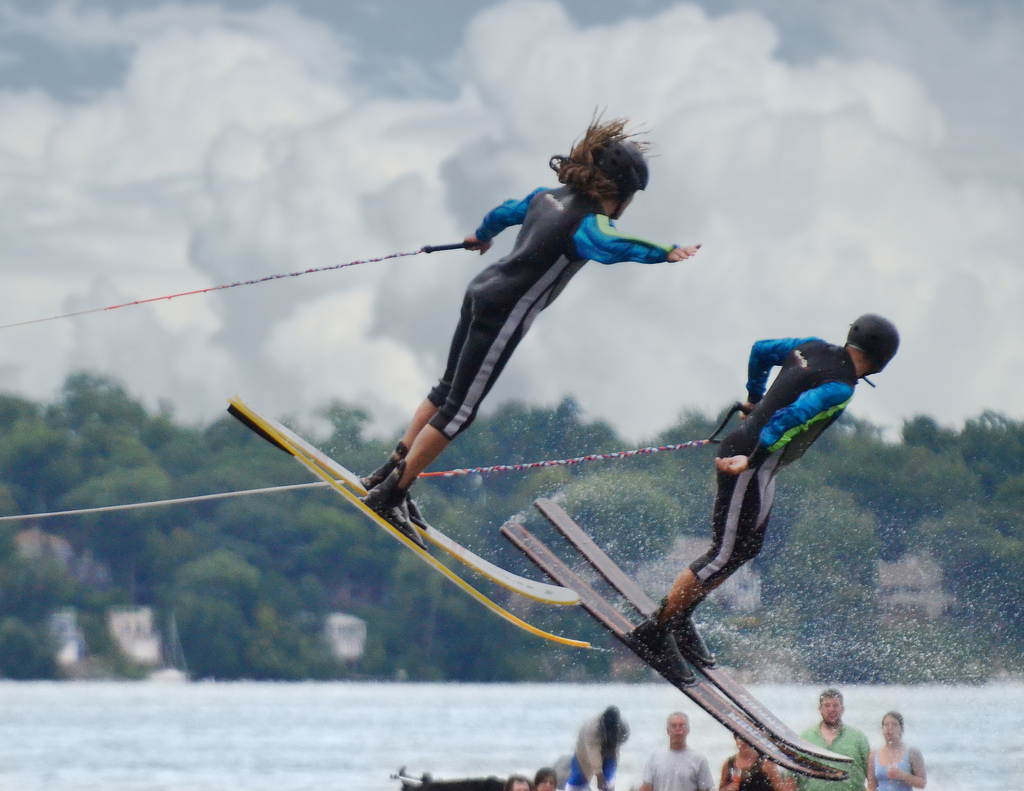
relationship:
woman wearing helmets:
[341, 119, 699, 563] [592, 57, 915, 408]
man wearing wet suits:
[627, 313, 902, 687] [688, 337, 855, 589]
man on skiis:
[627, 313, 902, 687] [491, 471, 863, 770]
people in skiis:
[361, 108, 701, 551] [4, 366, 597, 660]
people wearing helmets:
[371, 107, 906, 686] [560, 102, 904, 370]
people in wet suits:
[371, 107, 906, 686] [415, 188, 861, 588]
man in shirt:
[780, 679, 869, 772] [793, 716, 873, 783]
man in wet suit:
[627, 313, 902, 687] [346, 141, 871, 585]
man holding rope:
[627, 300, 934, 696] [0, 357, 767, 522]